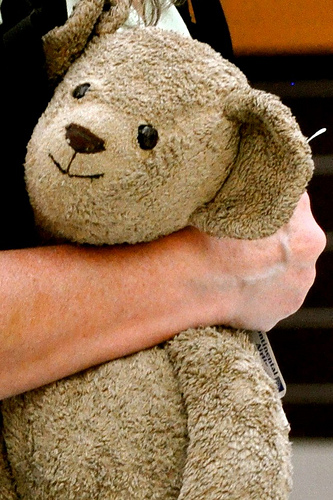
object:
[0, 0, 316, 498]
bear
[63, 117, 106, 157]
nose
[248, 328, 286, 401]
tag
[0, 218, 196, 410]
arm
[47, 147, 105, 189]
mouth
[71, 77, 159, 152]
eyes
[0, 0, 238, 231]
jacket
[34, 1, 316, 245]
ears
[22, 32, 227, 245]
face